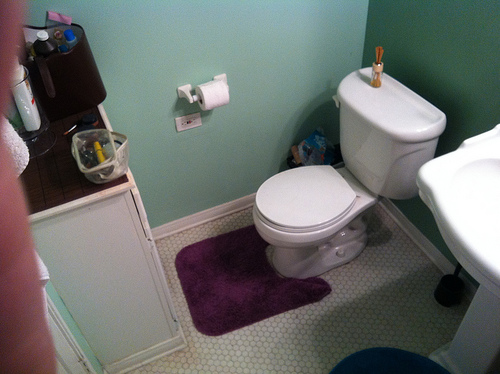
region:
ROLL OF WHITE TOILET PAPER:
[194, 77, 231, 112]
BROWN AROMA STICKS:
[369, 44, 385, 89]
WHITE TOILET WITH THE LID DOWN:
[248, 63, 445, 288]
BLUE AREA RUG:
[319, 338, 460, 371]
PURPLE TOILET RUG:
[172, 214, 334, 338]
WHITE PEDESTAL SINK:
[415, 103, 497, 371]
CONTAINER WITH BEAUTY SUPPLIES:
[21, 20, 105, 114]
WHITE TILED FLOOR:
[97, 174, 486, 371]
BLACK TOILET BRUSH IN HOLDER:
[431, 242, 466, 312]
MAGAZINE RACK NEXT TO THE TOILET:
[284, 127, 344, 166]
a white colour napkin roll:
[193, 82, 235, 105]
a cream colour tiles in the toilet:
[288, 315, 430, 339]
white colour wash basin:
[433, 156, 498, 288]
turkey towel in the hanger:
[10, 130, 26, 162]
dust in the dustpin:
[298, 139, 333, 159]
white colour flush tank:
[343, 65, 417, 188]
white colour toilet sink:
[261, 165, 373, 275]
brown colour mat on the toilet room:
[178, 245, 319, 316]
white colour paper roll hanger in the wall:
[173, 69, 239, 104]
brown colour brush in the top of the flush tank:
[371, 45, 384, 93]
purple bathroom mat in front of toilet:
[151, 221, 332, 336]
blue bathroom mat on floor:
[311, 316, 476, 367]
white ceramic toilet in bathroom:
[242, 47, 454, 297]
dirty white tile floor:
[263, 257, 429, 369]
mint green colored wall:
[111, 3, 336, 196]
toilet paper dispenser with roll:
[167, 70, 261, 117]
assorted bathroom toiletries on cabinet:
[0, 12, 97, 111]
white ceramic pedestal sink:
[401, 101, 498, 365]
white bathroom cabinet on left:
[52, 149, 187, 364]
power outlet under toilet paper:
[165, 105, 215, 158]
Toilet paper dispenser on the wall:
[126, 38, 303, 133]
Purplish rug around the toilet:
[166, 213, 354, 348]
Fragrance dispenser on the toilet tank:
[356, 26, 400, 103]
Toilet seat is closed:
[231, 111, 397, 283]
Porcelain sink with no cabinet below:
[393, 96, 499, 373]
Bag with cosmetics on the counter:
[46, 108, 145, 198]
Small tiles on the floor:
[325, 260, 435, 347]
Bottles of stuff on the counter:
[26, 13, 119, 128]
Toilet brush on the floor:
[414, 244, 473, 326]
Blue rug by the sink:
[306, 316, 455, 372]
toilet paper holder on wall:
[175, 70, 245, 120]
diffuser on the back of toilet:
[367, 42, 382, 92]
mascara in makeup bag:
[91, 140, 109, 162]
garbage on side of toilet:
[286, 132, 333, 159]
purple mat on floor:
[173, 229, 294, 326]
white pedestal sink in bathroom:
[414, 165, 499, 365]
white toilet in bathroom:
[258, 69, 423, 266]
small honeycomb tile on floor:
[267, 350, 277, 358]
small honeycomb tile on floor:
[327, 342, 339, 354]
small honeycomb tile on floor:
[241, 358, 248, 365]